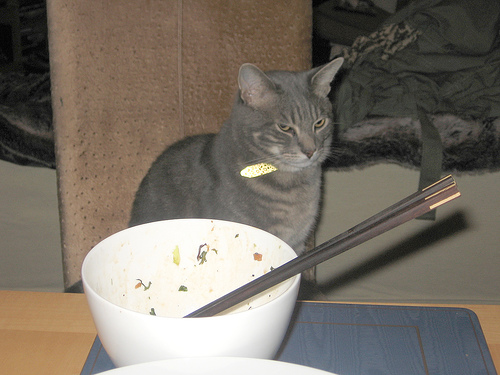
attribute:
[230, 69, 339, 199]
cat — gray, staring, sitting, grey, looking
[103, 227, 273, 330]
bowl — white, dirty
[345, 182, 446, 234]
chop stick — brown